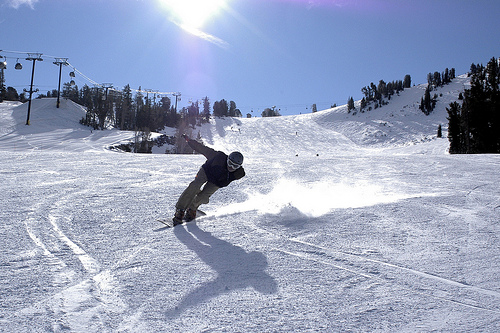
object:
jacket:
[187, 138, 246, 188]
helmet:
[227, 151, 244, 166]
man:
[157, 132, 245, 228]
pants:
[175, 167, 221, 211]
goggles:
[225, 158, 243, 171]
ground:
[0, 191, 254, 332]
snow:
[271, 237, 439, 332]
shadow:
[163, 219, 278, 319]